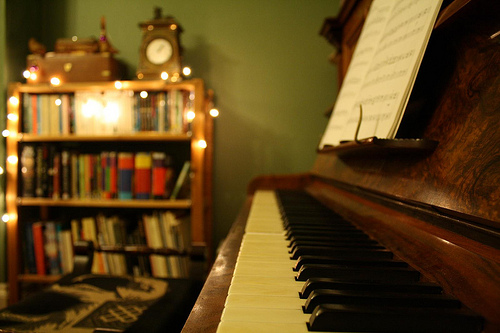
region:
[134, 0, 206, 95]
a gold clock on a shelf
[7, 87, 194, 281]
a bookcase filled with books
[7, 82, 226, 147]
twinkling white lights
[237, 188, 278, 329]
white ivory piano keys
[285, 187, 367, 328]
black piano keys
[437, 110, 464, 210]
dark swirled wood of a piano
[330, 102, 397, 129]
an open music book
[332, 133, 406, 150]
a brown wooden music stand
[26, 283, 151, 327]
a black and white rug on the floor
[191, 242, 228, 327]
the brown wood on the front ledge of a piano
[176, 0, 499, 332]
dark wood piano with sheet music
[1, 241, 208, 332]
wood bench with covering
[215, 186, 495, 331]
piano keys are white and black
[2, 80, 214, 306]
wood shelves behind bench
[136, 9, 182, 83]
clock on top of shelves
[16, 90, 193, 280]
books on shelves many sections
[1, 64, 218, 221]
many lights on shelves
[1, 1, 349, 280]
green wall behind piano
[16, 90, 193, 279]
books on shelves are many colors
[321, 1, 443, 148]
white sheets with black writing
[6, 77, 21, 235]
clear string of lights hanging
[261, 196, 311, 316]
black and white piano keys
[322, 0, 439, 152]
book of piano music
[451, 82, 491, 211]
dark and light wood grain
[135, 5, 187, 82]
clock against green wall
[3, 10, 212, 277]
book shelf unit with books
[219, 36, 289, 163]
shadows cast on olive green wall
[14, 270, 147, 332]
design in upholstery of piano bench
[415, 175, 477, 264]
reflection of light on piano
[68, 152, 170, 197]
books in various colors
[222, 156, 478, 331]
black and white piano keys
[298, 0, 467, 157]
music sheets on top of piano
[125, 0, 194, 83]
old fashioned clock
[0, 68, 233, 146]
white string lights framing bookshelf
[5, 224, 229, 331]
piano bench with patterned cushion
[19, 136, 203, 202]
multi colored books on shelf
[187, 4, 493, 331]
mahogany wood stained piano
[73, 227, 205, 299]
wooden handle on bench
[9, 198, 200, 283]
multiple tall books on shelf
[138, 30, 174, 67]
face of clock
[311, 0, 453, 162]
Sheet music on the piano.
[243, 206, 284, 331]
The keys are white.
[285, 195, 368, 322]
The keys are black.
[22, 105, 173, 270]
Books on a shelf.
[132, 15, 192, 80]
Clock on a shelf.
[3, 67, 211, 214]
Lights on the shelf.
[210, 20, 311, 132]
The wall is green.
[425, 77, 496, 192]
The piano is brown.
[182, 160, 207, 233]
The shelf is wooden.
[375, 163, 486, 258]
The piano is wooden.